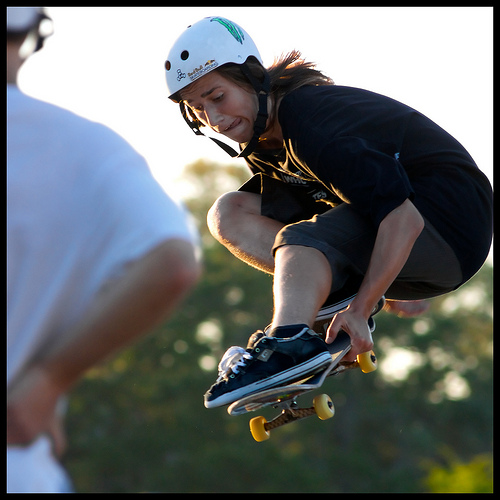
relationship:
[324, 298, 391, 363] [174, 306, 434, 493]
hand on skateboard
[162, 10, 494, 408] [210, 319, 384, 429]
man on board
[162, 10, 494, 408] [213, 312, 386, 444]
man on skate board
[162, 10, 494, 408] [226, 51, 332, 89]
man on hair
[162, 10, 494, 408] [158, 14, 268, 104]
man on helmet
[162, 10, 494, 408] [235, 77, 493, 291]
man on black shirt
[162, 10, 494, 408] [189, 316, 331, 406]
man on shoes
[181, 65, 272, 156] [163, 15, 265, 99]
strap of helmet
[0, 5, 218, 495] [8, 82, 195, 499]
person wearing shirt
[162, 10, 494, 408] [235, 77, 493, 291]
man wears black shirt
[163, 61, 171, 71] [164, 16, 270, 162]
hole on front of helmet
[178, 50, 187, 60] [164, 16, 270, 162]
hole on front of helmet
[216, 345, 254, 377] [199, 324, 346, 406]
laces on shoe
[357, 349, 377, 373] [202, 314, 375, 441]
wheel on skateboard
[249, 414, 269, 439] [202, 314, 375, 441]
wheel on skateboard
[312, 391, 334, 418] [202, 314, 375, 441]
wheel on skateboard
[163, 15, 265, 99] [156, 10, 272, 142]
helmet on head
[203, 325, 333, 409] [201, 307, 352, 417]
shoe wearing foot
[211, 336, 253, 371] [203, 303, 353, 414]
shoelaces wearing shoe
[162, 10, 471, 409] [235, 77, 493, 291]
man wearing black shirt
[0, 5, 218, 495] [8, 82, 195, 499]
person in shirt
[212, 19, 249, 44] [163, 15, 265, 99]
design on helmet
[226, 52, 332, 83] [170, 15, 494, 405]
hair on man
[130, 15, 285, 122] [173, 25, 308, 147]
helmet on head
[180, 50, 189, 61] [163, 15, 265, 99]
hole on helmet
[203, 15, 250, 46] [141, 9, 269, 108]
green logo on helmet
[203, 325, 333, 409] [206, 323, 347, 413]
shoe on feet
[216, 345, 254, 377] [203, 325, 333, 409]
laces from shoe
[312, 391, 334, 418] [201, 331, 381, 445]
wheel on skateboard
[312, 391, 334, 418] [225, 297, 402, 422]
wheel of skateboard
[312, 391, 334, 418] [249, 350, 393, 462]
wheel on trucks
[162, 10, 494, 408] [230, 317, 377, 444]
man riding skateboard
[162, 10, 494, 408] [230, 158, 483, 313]
man wearing shorts